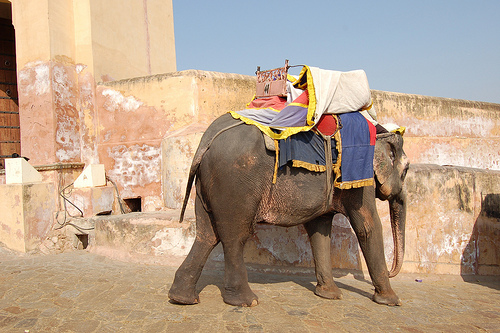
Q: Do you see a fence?
A: No, there are no fences.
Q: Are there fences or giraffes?
A: No, there are no fences or giraffes.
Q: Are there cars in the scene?
A: No, there are no cars.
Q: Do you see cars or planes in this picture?
A: No, there are no cars or planes.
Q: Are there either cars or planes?
A: No, there are no cars or planes.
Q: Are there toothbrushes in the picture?
A: No, there are no toothbrushes.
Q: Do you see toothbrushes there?
A: No, there are no toothbrushes.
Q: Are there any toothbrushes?
A: No, there are no toothbrushes.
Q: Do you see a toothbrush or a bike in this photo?
A: No, there are no toothbrushes or bikes.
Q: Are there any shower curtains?
A: No, there are no shower curtains.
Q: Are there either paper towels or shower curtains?
A: No, there are no shower curtains or paper towels.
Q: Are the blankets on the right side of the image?
A: Yes, the blankets are on the right of the image.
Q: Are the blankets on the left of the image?
A: No, the blankets are on the right of the image.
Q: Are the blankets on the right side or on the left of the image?
A: The blankets are on the right of the image.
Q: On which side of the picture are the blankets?
A: The blankets are on the right of the image.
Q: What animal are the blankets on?
A: The blankets are on the elephant.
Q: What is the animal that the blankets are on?
A: The animal is an elephant.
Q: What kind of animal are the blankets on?
A: The blankets are on the elephant.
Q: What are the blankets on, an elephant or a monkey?
A: The blankets are on an elephant.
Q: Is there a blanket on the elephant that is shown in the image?
A: Yes, there are blankets on the elephant.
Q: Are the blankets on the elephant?
A: Yes, the blankets are on the elephant.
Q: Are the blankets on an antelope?
A: No, the blankets are on the elephant.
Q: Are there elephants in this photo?
A: Yes, there is an elephant.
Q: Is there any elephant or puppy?
A: Yes, there is an elephant.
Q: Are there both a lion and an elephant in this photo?
A: No, there is an elephant but no lions.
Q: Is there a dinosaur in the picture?
A: No, there are no dinosaurs.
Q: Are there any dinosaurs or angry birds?
A: No, there are no dinosaurs or angry birds.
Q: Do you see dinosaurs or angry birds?
A: No, there are no dinosaurs or angry birds.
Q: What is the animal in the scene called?
A: The animal is an elephant.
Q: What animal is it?
A: The animal is an elephant.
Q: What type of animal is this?
A: This is an elephant.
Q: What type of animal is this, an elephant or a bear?
A: This is an elephant.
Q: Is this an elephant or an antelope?
A: This is an elephant.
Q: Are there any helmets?
A: No, there are no helmets.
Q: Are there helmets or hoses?
A: No, there are no helmets or hoses.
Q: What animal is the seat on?
A: The seat is on the elephant.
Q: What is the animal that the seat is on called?
A: The animal is an elephant.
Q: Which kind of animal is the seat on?
A: The seat is on the elephant.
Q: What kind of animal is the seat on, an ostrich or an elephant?
A: The seat is on an elephant.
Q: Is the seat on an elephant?
A: Yes, the seat is on an elephant.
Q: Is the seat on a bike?
A: No, the seat is on an elephant.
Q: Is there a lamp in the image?
A: No, there are no lamps.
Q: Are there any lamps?
A: No, there are no lamps.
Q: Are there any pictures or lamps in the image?
A: No, there are no lamps or pictures.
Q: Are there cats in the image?
A: No, there are no cats.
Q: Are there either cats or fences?
A: No, there are no cats or fences.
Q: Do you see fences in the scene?
A: No, there are no fences.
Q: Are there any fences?
A: No, there are no fences.